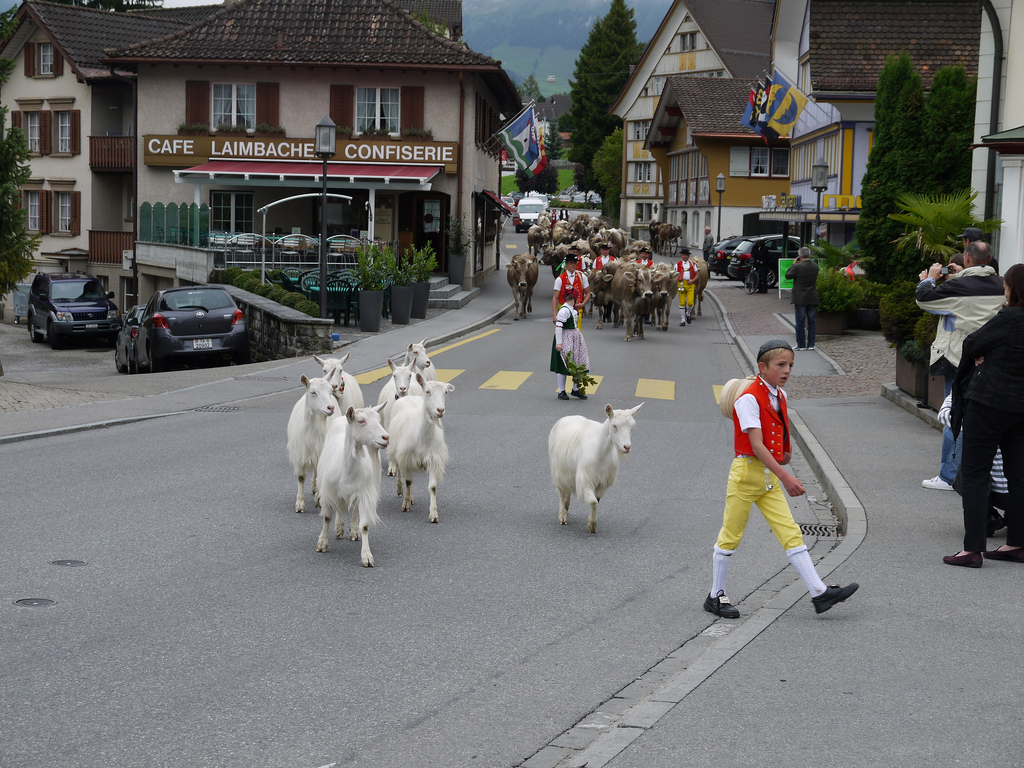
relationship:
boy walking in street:
[699, 336, 860, 622] [105, 268, 953, 755]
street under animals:
[80, 305, 856, 759] [291, 342, 655, 561]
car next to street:
[112, 282, 246, 371] [24, 325, 833, 762]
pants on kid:
[718, 453, 818, 553] [702, 344, 871, 636]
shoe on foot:
[695, 592, 741, 612] [695, 582, 743, 619]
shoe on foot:
[808, 577, 861, 617] [810, 573, 867, 615]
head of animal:
[339, 402, 392, 452] [319, 400, 402, 556]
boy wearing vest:
[700, 336, 861, 622] [734, 368, 791, 462]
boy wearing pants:
[700, 336, 861, 622] [723, 452, 817, 552]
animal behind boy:
[546, 401, 660, 527] [700, 336, 861, 622]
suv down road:
[30, 269, 124, 358] [8, 322, 246, 407]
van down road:
[514, 191, 547, 233] [503, 225, 707, 347]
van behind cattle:
[514, 191, 547, 233] [501, 202, 696, 328]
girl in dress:
[553, 290, 597, 399] [550, 312, 598, 384]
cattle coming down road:
[507, 204, 696, 336] [75, 227, 832, 759]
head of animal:
[604, 398, 644, 451] [533, 394, 670, 528]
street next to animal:
[15, 281, 806, 755] [546, 401, 660, 527]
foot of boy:
[805, 577, 860, 625] [699, 336, 860, 622]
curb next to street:
[540, 288, 858, 764] [78, 243, 813, 760]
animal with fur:
[533, 394, 670, 528] [551, 420, 591, 494]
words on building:
[144, 137, 443, 161] [127, 16, 517, 306]